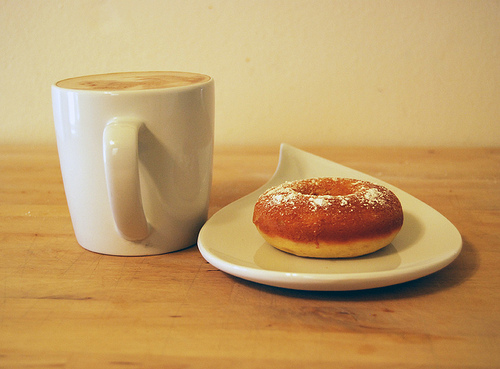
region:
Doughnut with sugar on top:
[248, 175, 407, 257]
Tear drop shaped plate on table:
[192, 138, 466, 297]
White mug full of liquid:
[49, 63, 212, 255]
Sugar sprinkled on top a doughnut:
[274, 191, 321, 210]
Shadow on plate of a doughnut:
[256, 241, 404, 281]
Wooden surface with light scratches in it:
[31, 268, 171, 355]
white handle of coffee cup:
[98, 119, 161, 247]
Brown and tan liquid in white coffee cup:
[56, 70, 213, 92]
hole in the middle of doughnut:
[299, 178, 363, 198]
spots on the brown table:
[308, 301, 427, 345]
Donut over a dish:
[242, 165, 415, 267]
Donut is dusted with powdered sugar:
[246, 163, 414, 267]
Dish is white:
[191, 122, 481, 307]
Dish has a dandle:
[190, 122, 474, 310]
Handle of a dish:
[253, 127, 345, 173]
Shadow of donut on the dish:
[402, 197, 436, 257]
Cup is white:
[39, 51, 224, 268]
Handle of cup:
[90, 105, 177, 253]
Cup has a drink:
[42, 56, 224, 268]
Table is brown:
[5, 131, 495, 365]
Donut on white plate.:
[239, 140, 474, 300]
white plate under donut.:
[222, 127, 417, 339]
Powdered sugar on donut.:
[234, 178, 415, 243]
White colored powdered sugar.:
[250, 175, 437, 230]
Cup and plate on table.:
[55, 52, 497, 320]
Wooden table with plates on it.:
[47, 255, 245, 351]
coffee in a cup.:
[31, 62, 218, 105]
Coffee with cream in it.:
[63, 63, 251, 93]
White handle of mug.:
[82, 117, 162, 244]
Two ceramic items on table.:
[21, 65, 466, 322]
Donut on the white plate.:
[247, 170, 476, 287]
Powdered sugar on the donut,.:
[265, 181, 417, 245]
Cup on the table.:
[23, 57, 243, 269]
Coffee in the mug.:
[43, 37, 248, 134]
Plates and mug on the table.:
[43, 60, 494, 347]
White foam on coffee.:
[50, 62, 219, 107]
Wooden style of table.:
[28, 242, 251, 353]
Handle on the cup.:
[100, 129, 187, 244]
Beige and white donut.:
[255, 168, 436, 305]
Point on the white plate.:
[268, 115, 351, 195]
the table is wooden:
[41, 265, 152, 349]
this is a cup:
[55, 75, 190, 255]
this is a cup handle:
[102, 119, 154, 234]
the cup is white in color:
[73, 97, 100, 224]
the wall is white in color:
[308, 60, 460, 124]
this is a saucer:
[201, 137, 465, 275]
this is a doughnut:
[249, 173, 408, 253]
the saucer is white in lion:
[293, 260, 408, 282]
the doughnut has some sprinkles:
[276, 197, 386, 208]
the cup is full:
[56, 73, 211, 90]